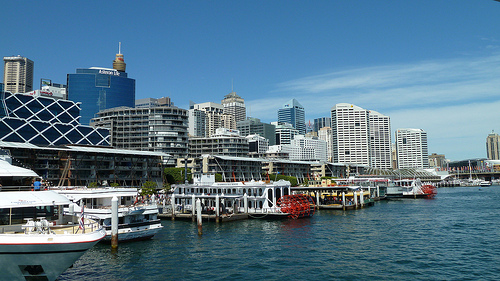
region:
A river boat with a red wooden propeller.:
[156, 173, 316, 220]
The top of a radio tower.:
[112, 40, 125, 74]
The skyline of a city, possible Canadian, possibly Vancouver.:
[0, 41, 497, 196]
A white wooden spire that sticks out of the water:
[109, 193, 121, 248]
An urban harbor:
[2, 179, 497, 279]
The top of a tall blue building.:
[278, 96, 305, 128]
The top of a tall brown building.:
[2, 53, 35, 98]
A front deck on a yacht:
[0, 208, 104, 235]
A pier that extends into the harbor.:
[287, 185, 371, 210]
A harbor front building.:
[0, 149, 169, 185]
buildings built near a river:
[23, 56, 303, 144]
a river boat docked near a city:
[234, 166, 316, 228]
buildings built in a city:
[155, 102, 327, 148]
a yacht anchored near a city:
[38, 175, 85, 249]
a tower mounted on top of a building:
[84, 41, 153, 58]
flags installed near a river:
[437, 157, 492, 181]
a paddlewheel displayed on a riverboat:
[273, 182, 316, 229]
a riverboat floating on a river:
[238, 165, 327, 230]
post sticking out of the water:
[108, 194, 135, 254]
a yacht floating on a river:
[27, 189, 115, 272]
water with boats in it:
[0, 181, 492, 266]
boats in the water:
[6, 163, 407, 233]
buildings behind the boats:
[0, 45, 496, 164]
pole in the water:
[104, 195, 141, 258]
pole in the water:
[182, 193, 204, 241]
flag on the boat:
[64, 195, 89, 233]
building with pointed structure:
[276, 93, 310, 132]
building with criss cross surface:
[6, 91, 113, 143]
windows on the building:
[341, 113, 360, 155]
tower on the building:
[223, 74, 238, 89]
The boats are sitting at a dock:
[7, 20, 457, 275]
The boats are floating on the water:
[12, 40, 477, 275]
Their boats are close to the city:
[20, 30, 478, 265]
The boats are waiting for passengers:
[5, 36, 456, 278]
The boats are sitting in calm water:
[22, 20, 477, 277]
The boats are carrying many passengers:
[2, 13, 492, 278]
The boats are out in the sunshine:
[20, 23, 490, 276]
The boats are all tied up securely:
[1, 30, 491, 266]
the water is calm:
[65, 185, 496, 279]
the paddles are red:
[277, 195, 313, 217]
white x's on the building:
[3, 92, 110, 145]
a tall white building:
[331, 104, 369, 166]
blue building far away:
[278, 97, 302, 127]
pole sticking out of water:
[109, 197, 118, 247]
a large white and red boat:
[161, 183, 313, 220]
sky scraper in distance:
[114, 42, 124, 70]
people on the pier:
[130, 192, 165, 204]